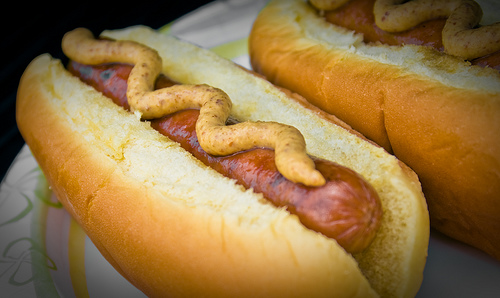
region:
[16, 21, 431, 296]
hot dog with mustard on bun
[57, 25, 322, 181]
line of spicy mustard on hot dog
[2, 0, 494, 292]
white paper plate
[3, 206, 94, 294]
green and yellow design on white paper plate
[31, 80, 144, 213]
tan bun with mustard sauce on the edge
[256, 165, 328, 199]
brown grill mark on hot dog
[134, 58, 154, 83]
brown seasoning in yellow mustard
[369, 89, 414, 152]
brown crease in hot dog bun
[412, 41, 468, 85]
spot of relish sauce on white hot dog bun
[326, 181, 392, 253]
end of hot dog link in bun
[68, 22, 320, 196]
stone ground yellow mustard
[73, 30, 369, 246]
grilled hot dog on bun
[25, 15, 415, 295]
hot dog in bun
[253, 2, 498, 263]
white bread hot dog bun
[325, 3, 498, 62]
yellow mustard on bun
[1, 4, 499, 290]
white paper plate with designs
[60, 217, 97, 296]
yellow line on paper plate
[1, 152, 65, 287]
green design on paper plate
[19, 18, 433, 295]
cooked hot dog on plate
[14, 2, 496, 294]
hot dogs in bun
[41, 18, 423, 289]
a sandwich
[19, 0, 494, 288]
Two hot dogs on a plate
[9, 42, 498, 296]
White paper plate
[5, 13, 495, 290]
Round plate with hot dogs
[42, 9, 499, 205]
Mustard on the hot dogs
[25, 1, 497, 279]
Hot dogs in buns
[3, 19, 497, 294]
Nobody in the picture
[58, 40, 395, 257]
The hot dog is brown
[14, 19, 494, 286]
Buns made from white bread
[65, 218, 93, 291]
Yellow line lining the paper plate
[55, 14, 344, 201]
The mustard is spicy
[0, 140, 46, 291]
edge of a paper plate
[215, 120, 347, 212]
mustard on a hotdog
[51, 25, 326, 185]
squiggle line of mustard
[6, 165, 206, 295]
hotdog bun and plate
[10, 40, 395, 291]
grilled wiener with mustard on a bun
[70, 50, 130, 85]
dark grill mark on a hotdog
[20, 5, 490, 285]
two frankfurters on a paper plate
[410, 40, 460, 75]
mustard stain on the bread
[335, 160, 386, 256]
round end of a wiener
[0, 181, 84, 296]
white paper plate with green designs